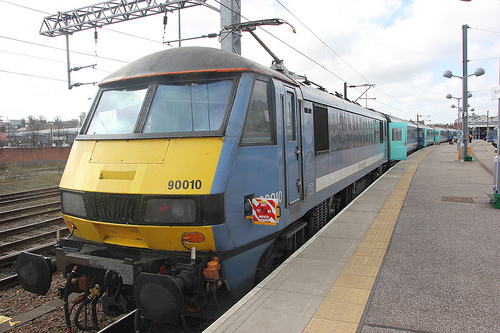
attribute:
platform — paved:
[387, 167, 497, 331]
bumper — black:
[135, 269, 182, 331]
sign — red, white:
[248, 198, 279, 227]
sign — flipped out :
[249, 198, 276, 226]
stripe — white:
[316, 151, 384, 191]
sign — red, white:
[252, 198, 279, 225]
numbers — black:
[163, 175, 208, 195]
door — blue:
[269, 92, 286, 192]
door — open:
[368, 91, 407, 181]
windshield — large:
[80, 66, 232, 139]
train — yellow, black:
[47, 52, 449, 261]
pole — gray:
[448, 20, 479, 167]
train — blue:
[6, 39, 472, 331]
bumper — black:
[9, 242, 219, 313]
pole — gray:
[215, 0, 245, 60]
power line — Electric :
[1, 0, 424, 114]